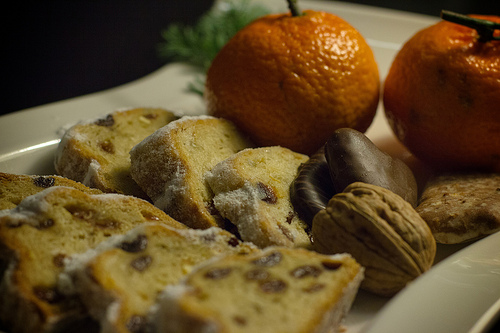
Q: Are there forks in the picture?
A: No, there are no forks.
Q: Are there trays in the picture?
A: No, there are no trays.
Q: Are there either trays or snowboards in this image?
A: No, there are no trays or snowboards.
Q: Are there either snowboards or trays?
A: No, there are no trays or snowboards.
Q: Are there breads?
A: Yes, there is a bread.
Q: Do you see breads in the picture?
A: Yes, there is a bread.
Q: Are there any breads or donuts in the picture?
A: Yes, there is a bread.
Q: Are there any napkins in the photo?
A: No, there are no napkins.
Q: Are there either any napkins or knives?
A: No, there are no napkins or knives.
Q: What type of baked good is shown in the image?
A: The baked good is a bread.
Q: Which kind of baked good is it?
A: The food is a bread.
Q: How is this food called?
A: That is a bread.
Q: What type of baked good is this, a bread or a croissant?
A: That is a bread.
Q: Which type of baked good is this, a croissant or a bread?
A: That is a bread.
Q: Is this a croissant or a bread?
A: This is a bread.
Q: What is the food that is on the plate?
A: The food is a bread.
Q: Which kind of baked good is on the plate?
A: The food is a bread.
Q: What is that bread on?
A: The bread is on the plate.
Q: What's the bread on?
A: The bread is on the plate.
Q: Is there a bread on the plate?
A: Yes, there is a bread on the plate.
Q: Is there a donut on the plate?
A: No, there is a bread on the plate.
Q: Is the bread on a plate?
A: Yes, the bread is on a plate.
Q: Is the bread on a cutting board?
A: No, the bread is on a plate.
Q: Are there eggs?
A: No, there are no eggs.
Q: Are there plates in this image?
A: Yes, there is a plate.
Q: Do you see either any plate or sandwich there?
A: Yes, there is a plate.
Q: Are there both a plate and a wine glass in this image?
A: No, there is a plate but no wine glasses.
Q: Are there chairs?
A: No, there are no chairs.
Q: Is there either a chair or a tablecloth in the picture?
A: No, there are no chairs or tablecloths.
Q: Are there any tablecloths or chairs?
A: No, there are no chairs or tablecloths.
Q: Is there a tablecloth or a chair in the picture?
A: No, there are no chairs or tablecloths.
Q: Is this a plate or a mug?
A: This is a plate.